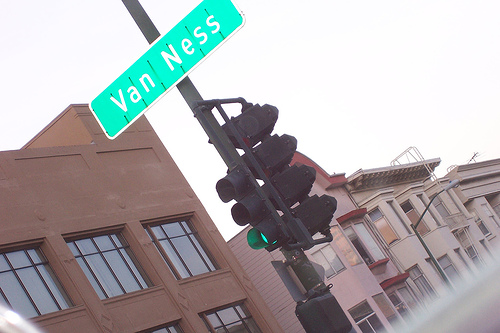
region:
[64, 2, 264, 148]
green and white street sign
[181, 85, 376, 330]
black traffic light on pole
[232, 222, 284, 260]
green traffic light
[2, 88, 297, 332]
stone building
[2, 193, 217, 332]
windows on stone building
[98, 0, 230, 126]
black lines in green street sign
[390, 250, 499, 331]
blurred white image in front of buildings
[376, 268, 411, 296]
red window covering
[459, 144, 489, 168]
antenna on top of building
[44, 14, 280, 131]
The sign says "Van Ness"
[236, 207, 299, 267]
This means go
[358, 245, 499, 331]
The side is blurry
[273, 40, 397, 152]
The time of day is daytime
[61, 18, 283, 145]
The sign is green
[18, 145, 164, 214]
Building is brown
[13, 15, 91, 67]
The sky is not clear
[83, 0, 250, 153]
Green street sign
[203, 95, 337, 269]
Traffic light showing green light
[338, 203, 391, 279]
Bay window on upper floor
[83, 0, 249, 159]
Van Ness street sign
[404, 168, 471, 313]
Street light located directly outside building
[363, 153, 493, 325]
Building with bay windows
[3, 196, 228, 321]
Brown building with paned windows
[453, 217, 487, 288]
Fire escape ladder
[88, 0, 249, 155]
Street sign with rusted nails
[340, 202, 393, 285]
Bay window with maroon awning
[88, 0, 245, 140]
the green street sign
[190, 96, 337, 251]
the traffic lights on the pole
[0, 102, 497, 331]
the buildings behind the traffic lights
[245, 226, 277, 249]
the light from the green traffic light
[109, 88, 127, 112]
the letter "V" on the street sign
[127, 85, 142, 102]
the letter "a" on the street sign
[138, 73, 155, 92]
the letter "n" on the street sign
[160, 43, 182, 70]
the letter "N" on the street sign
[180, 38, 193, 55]
the letter "e" on the street sign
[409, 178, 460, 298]
the street light near the building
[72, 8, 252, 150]
van ness street sign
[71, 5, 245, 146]
van ness street sign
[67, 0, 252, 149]
van ness street sign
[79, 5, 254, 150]
van ness street sign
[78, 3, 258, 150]
van ness street sign